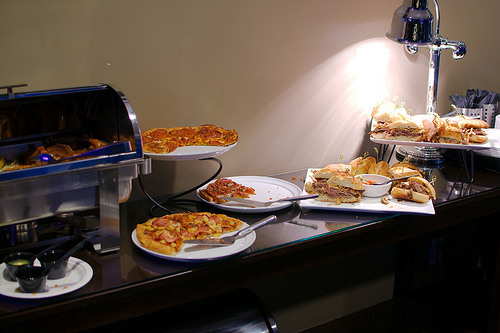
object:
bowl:
[15, 265, 47, 291]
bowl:
[46, 247, 71, 279]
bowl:
[1, 250, 34, 266]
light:
[397, 1, 467, 173]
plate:
[301, 164, 439, 215]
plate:
[366, 127, 494, 153]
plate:
[194, 172, 303, 213]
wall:
[184, 88, 430, 198]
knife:
[179, 215, 278, 250]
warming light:
[387, 5, 456, 65]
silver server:
[186, 213, 278, 248]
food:
[0, 111, 499, 253]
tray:
[0, 81, 152, 253]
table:
[0, 167, 498, 331]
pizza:
[196, 175, 255, 206]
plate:
[132, 213, 256, 260]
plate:
[146, 143, 239, 161]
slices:
[136, 116, 248, 164]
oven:
[0, 84, 152, 259]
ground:
[367, 137, 493, 218]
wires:
[137, 159, 203, 211]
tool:
[0, 74, 155, 263]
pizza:
[136, 210, 243, 255]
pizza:
[140, 120, 234, 151]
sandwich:
[307, 111, 497, 206]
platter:
[301, 165, 436, 215]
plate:
[0, 251, 98, 301]